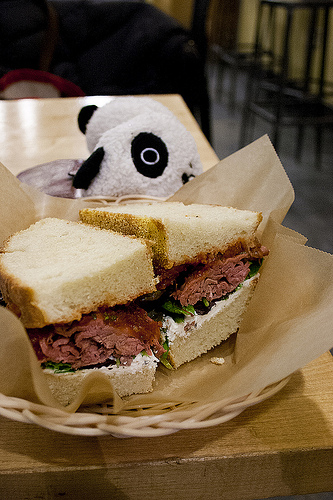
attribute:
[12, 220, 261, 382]
sandwhich — cut, broken, thick, crusty, clear, bread, crust, half, halfed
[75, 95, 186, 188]
stuffed animal — white, black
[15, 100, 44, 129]
table — brown, close, wood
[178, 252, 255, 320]
meat — sandwhich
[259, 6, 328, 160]
stool — black